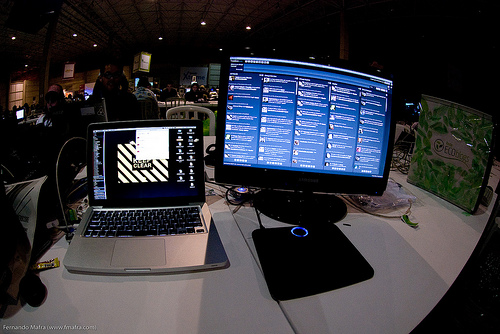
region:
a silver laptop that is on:
[67, 112, 239, 281]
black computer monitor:
[210, 51, 395, 201]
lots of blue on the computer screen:
[200, 53, 406, 200]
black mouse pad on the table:
[244, 218, 373, 316]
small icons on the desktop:
[170, 127, 196, 192]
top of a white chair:
[163, 104, 215, 134]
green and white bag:
[400, 86, 493, 225]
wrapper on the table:
[31, 258, 63, 270]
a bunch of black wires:
[389, 136, 418, 172]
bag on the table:
[403, 92, 493, 222]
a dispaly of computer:
[217, 55, 419, 187]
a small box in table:
[250, 220, 377, 318]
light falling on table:
[279, 216, 324, 250]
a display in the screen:
[223, 64, 405, 194]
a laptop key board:
[88, 209, 217, 242]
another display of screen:
[69, 110, 225, 216]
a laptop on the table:
[70, 108, 240, 305]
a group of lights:
[65, 8, 280, 58]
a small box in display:
[95, 125, 215, 207]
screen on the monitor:
[229, 55, 389, 181]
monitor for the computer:
[220, 55, 394, 200]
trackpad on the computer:
[102, 235, 171, 265]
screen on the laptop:
[80, 132, 197, 197]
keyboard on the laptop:
[85, 207, 202, 237]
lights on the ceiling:
[42, 20, 240, 47]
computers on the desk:
[124, 203, 410, 298]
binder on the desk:
[411, 92, 477, 215]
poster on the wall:
[131, 50, 158, 80]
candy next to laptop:
[28, 240, 63, 278]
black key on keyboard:
[98, 211, 106, 217]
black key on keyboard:
[103, 210, 114, 217]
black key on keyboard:
[118, 208, 128, 216]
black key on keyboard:
[85, 228, 94, 237]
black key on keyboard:
[91, 228, 98, 236]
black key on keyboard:
[98, 230, 107, 235]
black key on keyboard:
[104, 228, 114, 238]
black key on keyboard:
[164, 211, 171, 219]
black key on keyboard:
[176, 206, 183, 213]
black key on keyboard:
[187, 225, 197, 233]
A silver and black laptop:
[62, 119, 232, 274]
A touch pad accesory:
[251, 220, 373, 300]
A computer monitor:
[215, 45, 400, 224]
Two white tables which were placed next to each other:
[14, 135, 498, 331]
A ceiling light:
[198, 18, 209, 26]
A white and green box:
[405, 97, 491, 211]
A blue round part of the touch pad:
[287, 224, 311, 239]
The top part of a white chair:
[164, 105, 216, 137]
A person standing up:
[191, 75, 198, 86]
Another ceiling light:
[70, 30, 78, 39]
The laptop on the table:
[62, 118, 232, 276]